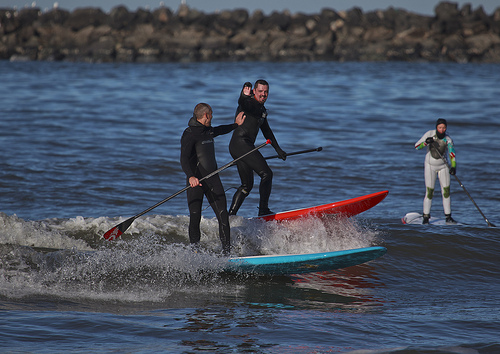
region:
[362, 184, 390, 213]
top of red board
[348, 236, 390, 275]
top of blue board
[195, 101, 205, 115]
man has brown hair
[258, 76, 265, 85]
man has black hair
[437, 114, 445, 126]
woman wearing face mask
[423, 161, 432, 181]
woman wearing white pants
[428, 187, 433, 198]
green patch on pants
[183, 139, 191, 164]
man wearing black shirt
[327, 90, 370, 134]
small waves in water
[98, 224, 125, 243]
red and white paddle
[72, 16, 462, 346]
men paddle boarding on water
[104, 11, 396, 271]
two men paddle boarding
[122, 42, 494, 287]
two men on paddle boards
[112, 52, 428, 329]
men on paddle boards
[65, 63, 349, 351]
a blue paddle board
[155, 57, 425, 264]
a red paddle board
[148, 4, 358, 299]
a black wet suit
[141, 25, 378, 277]
two men holding paddles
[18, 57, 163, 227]
a body of water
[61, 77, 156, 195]
a body of calm water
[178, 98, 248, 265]
The paddle boarder on the left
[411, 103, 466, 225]
the paddle boarder in white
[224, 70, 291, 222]
The paddle boarder in the middle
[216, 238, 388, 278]
The bright blue paddle board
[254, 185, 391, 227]
The red paddle board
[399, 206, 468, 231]
The white paddle board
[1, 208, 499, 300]
The wave the paddle boarders are on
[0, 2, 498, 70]
The rock jetty behind the boarders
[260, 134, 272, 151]
The red tip of a paddle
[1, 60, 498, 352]
The water the boarders are on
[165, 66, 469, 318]
three people on surfboards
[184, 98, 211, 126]
man has dark hair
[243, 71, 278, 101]
man has brown hair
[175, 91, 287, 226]
men have black wetsuits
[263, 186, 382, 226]
man has red surfboard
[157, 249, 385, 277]
man has blue surfboard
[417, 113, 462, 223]
person has white wetsuit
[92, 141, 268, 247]
man has black and red paddle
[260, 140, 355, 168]
man has black paddle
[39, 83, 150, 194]
water behind people is calm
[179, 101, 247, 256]
A man in a wet suit.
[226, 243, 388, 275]
A blue surfboard in the water.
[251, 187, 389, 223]
A red surfboard in the water.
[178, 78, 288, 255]
Two men in wet suits.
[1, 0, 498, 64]
Rocks in the ocean.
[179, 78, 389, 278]
Two men on surfboards.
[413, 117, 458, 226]
A women in a wet suit.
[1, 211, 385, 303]
White waves in the water.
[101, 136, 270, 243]
A red and black oar.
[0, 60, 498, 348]
A dark blue sea.